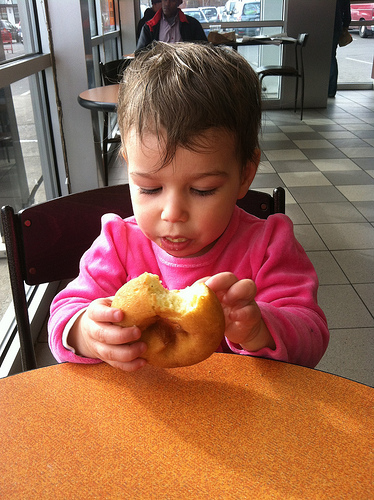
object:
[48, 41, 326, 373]
child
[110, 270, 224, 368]
donut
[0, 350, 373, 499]
table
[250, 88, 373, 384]
floor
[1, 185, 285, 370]
chair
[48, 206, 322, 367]
shirt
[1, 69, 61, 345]
window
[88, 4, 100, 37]
window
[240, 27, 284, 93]
window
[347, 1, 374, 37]
vehicle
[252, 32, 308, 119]
chair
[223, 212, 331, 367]
sleeve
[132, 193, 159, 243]
cheek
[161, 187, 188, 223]
nose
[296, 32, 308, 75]
back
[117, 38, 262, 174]
hair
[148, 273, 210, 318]
bite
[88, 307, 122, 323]
finger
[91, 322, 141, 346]
finger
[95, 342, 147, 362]
finger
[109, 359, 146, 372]
finger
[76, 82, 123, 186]
table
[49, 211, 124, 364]
sleeve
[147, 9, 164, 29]
collar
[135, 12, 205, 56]
jacket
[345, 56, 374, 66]
line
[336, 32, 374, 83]
street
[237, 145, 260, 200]
ear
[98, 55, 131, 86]
chair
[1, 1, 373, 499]
restaurant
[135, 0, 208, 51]
man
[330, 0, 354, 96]
person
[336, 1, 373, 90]
door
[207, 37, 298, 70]
table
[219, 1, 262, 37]
vehicle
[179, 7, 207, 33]
vehicle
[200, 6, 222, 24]
vehicle